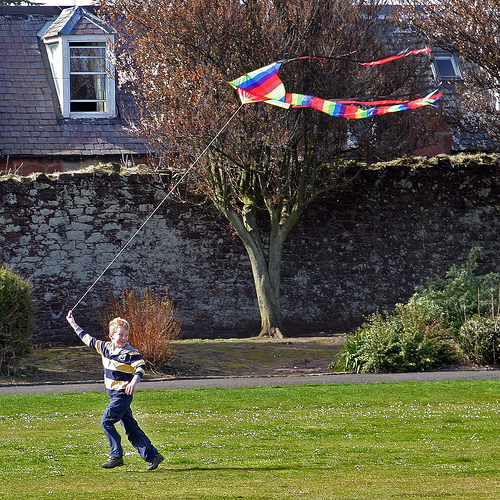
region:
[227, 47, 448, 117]
the kite in the sky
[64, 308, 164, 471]
the boy holding the kite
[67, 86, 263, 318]
the kite strings attached to the kite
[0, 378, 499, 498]
the green grass around the boy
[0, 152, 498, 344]
the tall brick wall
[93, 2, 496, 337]
the trees near the brick wall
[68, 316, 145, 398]
the striped shirt on the boy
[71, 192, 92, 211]
gray rock on wall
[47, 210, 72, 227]
gray rock on wall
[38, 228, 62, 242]
gray rock on wall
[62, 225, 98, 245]
gray rock on wall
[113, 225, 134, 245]
gray rock on wall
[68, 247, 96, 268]
gray rock on wall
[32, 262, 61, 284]
gray rock on wall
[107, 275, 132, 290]
gray rock on wall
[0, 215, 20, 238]
gray rock on wall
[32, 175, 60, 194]
gray rock on wall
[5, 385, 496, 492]
The grassy area.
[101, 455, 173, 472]
The boy is wearing black shoes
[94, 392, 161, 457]
The boy is wearing a blue pant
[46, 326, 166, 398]
The boy is wearing a blue and yellow shirt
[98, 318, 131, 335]
The boy has blonde hair.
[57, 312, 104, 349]
The left hand of the boy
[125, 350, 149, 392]
The right hand of the boy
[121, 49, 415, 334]
The tree in the background.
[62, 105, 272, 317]
The string for the kite.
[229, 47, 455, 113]
The colorful kite.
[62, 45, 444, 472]
boy flying a kite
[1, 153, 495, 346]
stone wall separating house from field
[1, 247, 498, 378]
plants near the wall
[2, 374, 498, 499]
grass in the field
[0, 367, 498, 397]
path between the wall and field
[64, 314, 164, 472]
young boy in striped shirt and jeans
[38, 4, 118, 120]
window in the house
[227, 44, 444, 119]
multi-colored kite flying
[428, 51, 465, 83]
skylight on the roof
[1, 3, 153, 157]
portions of roof of the house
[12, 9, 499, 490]
a scene during the day time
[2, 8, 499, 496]
a scene outside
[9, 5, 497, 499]
an image of a yard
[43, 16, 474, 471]
a kid holding a kite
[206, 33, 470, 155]
a multi colored kite in the air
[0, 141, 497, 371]
a gray stone wall in the background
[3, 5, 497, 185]
a building in the background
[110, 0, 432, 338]
a tree next to wall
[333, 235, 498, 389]
green bushes on the right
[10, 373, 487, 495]
a green yard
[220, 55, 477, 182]
the kite is flying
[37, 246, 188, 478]
boy flying a kite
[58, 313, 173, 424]
the shirt is stripe